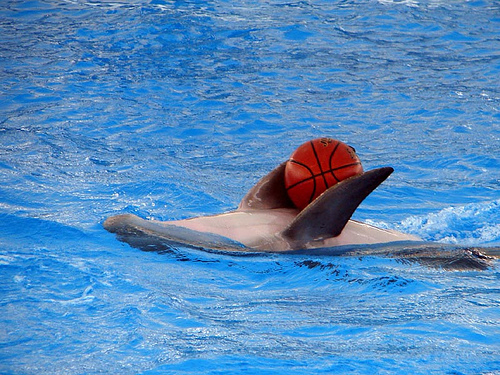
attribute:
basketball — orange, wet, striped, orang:
[283, 137, 362, 211]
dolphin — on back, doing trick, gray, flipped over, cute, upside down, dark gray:
[101, 157, 499, 290]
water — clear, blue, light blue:
[1, 1, 499, 372]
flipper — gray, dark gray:
[274, 165, 394, 239]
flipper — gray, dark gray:
[239, 159, 302, 210]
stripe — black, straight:
[283, 160, 362, 191]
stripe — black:
[308, 137, 330, 191]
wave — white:
[365, 196, 499, 236]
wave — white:
[432, 221, 498, 248]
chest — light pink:
[159, 208, 299, 253]